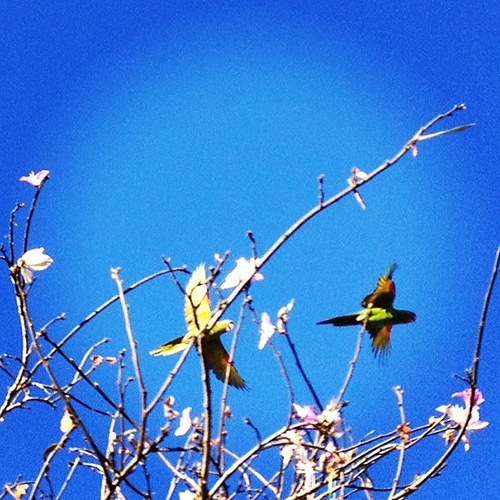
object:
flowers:
[7, 247, 55, 285]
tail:
[149, 331, 191, 356]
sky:
[1, 0, 183, 139]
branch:
[175, 104, 476, 369]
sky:
[218, 161, 290, 220]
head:
[398, 309, 417, 324]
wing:
[360, 260, 400, 308]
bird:
[315, 259, 418, 367]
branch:
[341, 305, 371, 388]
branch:
[178, 382, 234, 451]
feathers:
[365, 323, 393, 367]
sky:
[270, 0, 500, 115]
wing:
[365, 321, 393, 371]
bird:
[147, 262, 252, 396]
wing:
[195, 337, 253, 393]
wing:
[183, 260, 212, 332]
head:
[220, 318, 236, 333]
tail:
[315, 311, 364, 327]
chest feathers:
[355, 307, 395, 324]